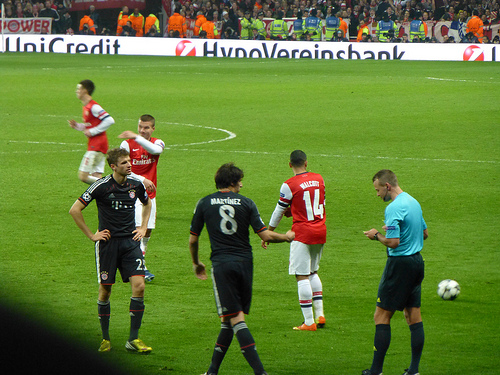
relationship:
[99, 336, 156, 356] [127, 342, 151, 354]
cleats are two colors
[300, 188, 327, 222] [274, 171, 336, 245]
number on shirt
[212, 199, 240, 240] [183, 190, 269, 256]
number on shirt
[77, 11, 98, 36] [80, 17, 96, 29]
people wearing jumpsuit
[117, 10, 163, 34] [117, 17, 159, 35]
people wearing jumpsuit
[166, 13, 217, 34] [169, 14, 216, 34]
people wearing jumpsuit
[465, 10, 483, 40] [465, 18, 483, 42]
people wearing jumpsuit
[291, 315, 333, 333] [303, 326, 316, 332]
cleats are color orange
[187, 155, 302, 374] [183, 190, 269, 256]
man in number eight shirt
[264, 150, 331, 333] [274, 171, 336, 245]
man in number fourteen shirt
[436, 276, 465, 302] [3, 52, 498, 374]
soccerball on field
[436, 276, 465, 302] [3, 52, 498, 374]
soccerball on turf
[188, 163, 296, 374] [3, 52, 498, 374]
man are on field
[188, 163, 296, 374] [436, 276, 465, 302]
man playing soccer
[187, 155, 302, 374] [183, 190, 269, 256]
man wearing a uniform shirt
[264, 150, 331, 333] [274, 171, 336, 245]
man wearing a uniform shirt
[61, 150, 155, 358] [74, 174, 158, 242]
man wearing a uniform shirt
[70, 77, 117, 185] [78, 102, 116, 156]
man wearing a uniform shirt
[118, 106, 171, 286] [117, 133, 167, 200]
man wearing a uniform shirt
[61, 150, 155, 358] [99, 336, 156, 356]
man wearing yellow cleats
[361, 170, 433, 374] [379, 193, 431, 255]
man wearing blue shirt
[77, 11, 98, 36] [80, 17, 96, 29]
person wearing orange jumpsuit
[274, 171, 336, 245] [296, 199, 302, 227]
uniform shirt red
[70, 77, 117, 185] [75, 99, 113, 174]
man running in red unifrom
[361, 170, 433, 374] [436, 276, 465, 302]
man near soccerball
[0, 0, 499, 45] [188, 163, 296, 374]
people who are watching man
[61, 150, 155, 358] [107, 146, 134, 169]
man with blonde hair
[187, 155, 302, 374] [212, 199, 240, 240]
man with  number eight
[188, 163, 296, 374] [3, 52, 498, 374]
man on field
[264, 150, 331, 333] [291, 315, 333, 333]
man with orange shoes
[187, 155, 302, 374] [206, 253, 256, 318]
man wearing blue shorts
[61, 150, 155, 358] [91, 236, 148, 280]
man wearing blue shorts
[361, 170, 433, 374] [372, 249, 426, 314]
man wearing blue shorts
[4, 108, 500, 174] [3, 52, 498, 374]
lines in field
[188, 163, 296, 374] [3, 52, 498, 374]
man on green grass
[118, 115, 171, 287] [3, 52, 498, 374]
man on field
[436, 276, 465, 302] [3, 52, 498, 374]
soccerball on grass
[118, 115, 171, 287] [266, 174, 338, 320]
man wearing soccer uniforms